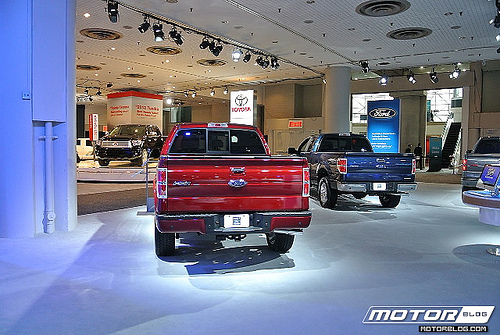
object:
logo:
[232, 92, 250, 108]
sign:
[361, 303, 495, 334]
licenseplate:
[222, 212, 250, 230]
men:
[410, 141, 425, 171]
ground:
[0, 178, 499, 334]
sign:
[284, 118, 306, 130]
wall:
[262, 82, 296, 156]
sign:
[363, 99, 400, 155]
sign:
[227, 89, 254, 126]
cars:
[144, 123, 373, 259]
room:
[0, 0, 500, 334]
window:
[163, 127, 209, 157]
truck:
[92, 122, 167, 165]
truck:
[151, 120, 313, 258]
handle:
[229, 167, 246, 176]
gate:
[161, 156, 305, 213]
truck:
[285, 130, 416, 212]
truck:
[458, 134, 499, 211]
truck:
[73, 138, 98, 163]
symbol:
[223, 178, 249, 190]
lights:
[135, 13, 152, 35]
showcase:
[2, 66, 499, 258]